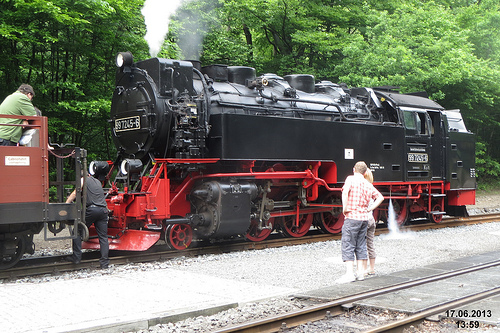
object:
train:
[0, 51, 478, 270]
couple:
[335, 159, 385, 285]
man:
[63, 168, 113, 269]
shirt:
[0, 90, 41, 142]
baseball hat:
[76, 167, 94, 178]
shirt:
[341, 174, 380, 220]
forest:
[0, 0, 499, 192]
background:
[0, 1, 500, 203]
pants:
[341, 219, 373, 261]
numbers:
[113, 115, 144, 135]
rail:
[367, 285, 500, 332]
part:
[355, 312, 425, 331]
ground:
[3, 196, 500, 329]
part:
[319, 258, 499, 310]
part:
[341, 221, 361, 260]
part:
[369, 182, 382, 202]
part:
[21, 99, 40, 117]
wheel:
[167, 221, 198, 253]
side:
[150, 58, 477, 252]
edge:
[340, 257, 359, 265]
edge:
[165, 160, 483, 253]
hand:
[364, 204, 371, 212]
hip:
[345, 216, 370, 226]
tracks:
[220, 257, 500, 332]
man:
[0, 84, 45, 147]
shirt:
[76, 176, 112, 210]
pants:
[72, 204, 112, 265]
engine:
[154, 55, 379, 251]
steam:
[140, 0, 222, 63]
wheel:
[280, 191, 318, 237]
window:
[398, 105, 433, 136]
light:
[115, 50, 127, 69]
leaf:
[293, 33, 304, 45]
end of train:
[103, 49, 170, 165]